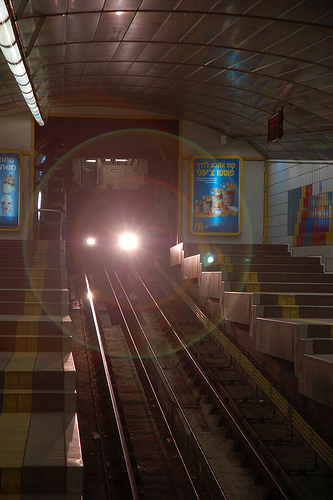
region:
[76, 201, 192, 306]
train headlights coming on tracks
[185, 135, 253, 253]
mcdonalds advertisement in foreign language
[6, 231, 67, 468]
yellow line coming down concrete stairs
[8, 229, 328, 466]
two sets of concrete stairs in photo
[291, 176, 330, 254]
colored tiles on wall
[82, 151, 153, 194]
window of train visible in photo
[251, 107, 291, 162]
black sign with red lettering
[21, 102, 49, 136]
lights on ceiling turned on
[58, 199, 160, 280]
one headlight bigger than the other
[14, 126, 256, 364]
two circles around headlights in photo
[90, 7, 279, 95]
metal rectangles on the ceiling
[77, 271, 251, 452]
a set of tracks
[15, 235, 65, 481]
a set of stairs on the left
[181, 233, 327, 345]
a set of stairs on the right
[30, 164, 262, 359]
glowing orbs from the light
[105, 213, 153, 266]
a bright white light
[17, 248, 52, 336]
a yellow strip down the stairs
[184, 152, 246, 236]
a Mcdonald's advertisement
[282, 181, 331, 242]
a colorful image on the tiled wall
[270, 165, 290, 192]
white tiles on the wall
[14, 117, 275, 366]
Halo effect from lens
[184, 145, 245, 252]
Mcdonald's advertisement in a language other than english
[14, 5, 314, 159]
Metal tiles on arched ceiling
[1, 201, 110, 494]
Stairway to the railroad tracks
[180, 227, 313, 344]
Yellow stripe on stairs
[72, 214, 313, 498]
Train headed down the tracks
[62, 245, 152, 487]
Shiny steel railroad track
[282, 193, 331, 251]
Colorful tiles on the wall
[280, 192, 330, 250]
Yellow, red, blue and orange tiles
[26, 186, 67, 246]
Steel bar to prevent fall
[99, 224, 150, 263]
A large light is shining.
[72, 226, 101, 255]
A small light is shining.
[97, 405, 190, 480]
The tracks are black.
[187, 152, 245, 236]
Poster on a wall.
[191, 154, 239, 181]
The writing is not in English.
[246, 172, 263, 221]
The wall is white.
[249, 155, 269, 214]
The pipes are yellow.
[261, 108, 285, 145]
Monitor hanging from the ceiling.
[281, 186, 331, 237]
Multicolored tiles on the wall.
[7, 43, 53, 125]
Lights on the ceiling.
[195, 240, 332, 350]
Brown steps with double yellow stripes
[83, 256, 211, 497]
Underground steel train tracks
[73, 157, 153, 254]
White underground truck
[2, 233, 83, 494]
White, black, yellow, and gray striped stairs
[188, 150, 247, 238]
Large blue and yellow poster hanging on the wall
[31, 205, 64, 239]
Silver grab bar on left side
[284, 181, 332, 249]
Blue, yellow, red, white, and orange colored tiles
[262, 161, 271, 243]
Yellow metal piping in right corner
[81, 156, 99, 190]
Open doorway on underground train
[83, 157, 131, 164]
Lights shining brightly in underground train